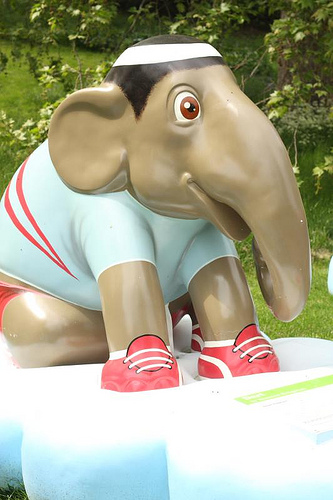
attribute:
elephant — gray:
[0, 34, 312, 392]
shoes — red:
[101, 322, 280, 392]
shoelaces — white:
[121, 337, 273, 372]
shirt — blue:
[1, 138, 241, 312]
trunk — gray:
[193, 85, 311, 323]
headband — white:
[112, 42, 223, 68]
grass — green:
[1, 12, 333, 340]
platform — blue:
[1, 336, 331, 499]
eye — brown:
[179, 95, 200, 121]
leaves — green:
[1, 0, 332, 194]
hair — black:
[106, 34, 230, 124]